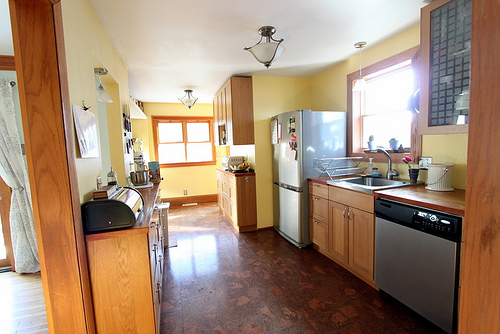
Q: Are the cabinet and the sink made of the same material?
A: No, the cabinet is made of wood and the sink is made of metal.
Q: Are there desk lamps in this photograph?
A: No, there are no desk lamps.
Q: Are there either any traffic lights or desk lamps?
A: No, there are no desk lamps or traffic lights.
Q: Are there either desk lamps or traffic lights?
A: No, there are no desk lamps or traffic lights.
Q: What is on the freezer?
A: The magnets are on the freezer.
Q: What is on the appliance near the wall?
A: The magnets are on the freezer.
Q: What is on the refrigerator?
A: The magnets are on the freezer.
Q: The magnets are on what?
A: The magnets are on the refrigerator.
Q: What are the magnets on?
A: The magnets are on the refrigerator.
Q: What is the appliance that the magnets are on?
A: The appliance is a refrigerator.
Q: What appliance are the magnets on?
A: The magnets are on the freezer.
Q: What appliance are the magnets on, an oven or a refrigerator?
A: The magnets are on a refrigerator.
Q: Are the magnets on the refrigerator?
A: Yes, the magnets are on the refrigerator.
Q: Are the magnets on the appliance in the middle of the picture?
A: Yes, the magnets are on the refrigerator.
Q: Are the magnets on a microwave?
A: No, the magnets are on the refrigerator.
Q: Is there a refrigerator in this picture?
A: Yes, there is a refrigerator.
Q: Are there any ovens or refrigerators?
A: Yes, there is a refrigerator.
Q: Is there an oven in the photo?
A: No, there are no ovens.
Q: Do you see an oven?
A: No, there are no ovens.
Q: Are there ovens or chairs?
A: No, there are no ovens or chairs.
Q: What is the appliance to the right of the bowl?
A: The appliance is a refrigerator.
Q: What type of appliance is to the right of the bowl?
A: The appliance is a refrigerator.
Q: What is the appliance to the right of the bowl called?
A: The appliance is a refrigerator.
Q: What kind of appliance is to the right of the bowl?
A: The appliance is a refrigerator.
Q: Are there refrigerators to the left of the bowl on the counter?
A: No, the refrigerator is to the right of the bowl.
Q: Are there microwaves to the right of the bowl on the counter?
A: No, there is a refrigerator to the right of the bowl.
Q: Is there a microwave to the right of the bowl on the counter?
A: No, there is a refrigerator to the right of the bowl.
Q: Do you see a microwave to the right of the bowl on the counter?
A: No, there is a refrigerator to the right of the bowl.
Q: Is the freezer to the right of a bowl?
A: Yes, the freezer is to the right of a bowl.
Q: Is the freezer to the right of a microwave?
A: No, the freezer is to the right of a bowl.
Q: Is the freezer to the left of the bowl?
A: No, the freezer is to the right of the bowl.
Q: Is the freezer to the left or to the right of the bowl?
A: The freezer is to the right of the bowl.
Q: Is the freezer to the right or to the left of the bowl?
A: The freezer is to the right of the bowl.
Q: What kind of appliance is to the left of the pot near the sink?
A: The appliance is a refrigerator.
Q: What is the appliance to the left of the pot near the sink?
A: The appliance is a refrigerator.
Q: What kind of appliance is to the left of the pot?
A: The appliance is a refrigerator.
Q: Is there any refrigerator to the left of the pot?
A: Yes, there is a refrigerator to the left of the pot.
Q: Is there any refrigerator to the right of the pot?
A: No, the refrigerator is to the left of the pot.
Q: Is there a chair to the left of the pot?
A: No, there is a refrigerator to the left of the pot.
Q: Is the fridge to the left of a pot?
A: Yes, the fridge is to the left of a pot.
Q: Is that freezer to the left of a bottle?
A: No, the freezer is to the left of a pot.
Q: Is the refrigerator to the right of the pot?
A: No, the refrigerator is to the left of the pot.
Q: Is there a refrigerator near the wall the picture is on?
A: Yes, there is a refrigerator near the wall.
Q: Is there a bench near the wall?
A: No, there is a refrigerator near the wall.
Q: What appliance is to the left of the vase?
A: The appliance is a refrigerator.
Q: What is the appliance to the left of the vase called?
A: The appliance is a refrigerator.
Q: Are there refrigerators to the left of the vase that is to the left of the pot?
A: Yes, there is a refrigerator to the left of the vase.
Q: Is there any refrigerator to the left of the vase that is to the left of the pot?
A: Yes, there is a refrigerator to the left of the vase.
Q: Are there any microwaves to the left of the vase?
A: No, there is a refrigerator to the left of the vase.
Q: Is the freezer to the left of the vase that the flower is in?
A: Yes, the freezer is to the left of the vase.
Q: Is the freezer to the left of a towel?
A: No, the freezer is to the left of the vase.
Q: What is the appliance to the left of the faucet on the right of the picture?
A: The appliance is a refrigerator.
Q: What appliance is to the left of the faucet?
A: The appliance is a refrigerator.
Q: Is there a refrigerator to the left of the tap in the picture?
A: Yes, there is a refrigerator to the left of the tap.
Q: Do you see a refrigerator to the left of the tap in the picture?
A: Yes, there is a refrigerator to the left of the tap.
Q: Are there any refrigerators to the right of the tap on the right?
A: No, the refrigerator is to the left of the tap.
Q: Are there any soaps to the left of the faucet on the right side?
A: No, there is a refrigerator to the left of the tap.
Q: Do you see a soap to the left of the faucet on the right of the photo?
A: No, there is a refrigerator to the left of the tap.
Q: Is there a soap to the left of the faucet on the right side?
A: No, there is a refrigerator to the left of the tap.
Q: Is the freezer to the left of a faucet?
A: Yes, the freezer is to the left of a faucet.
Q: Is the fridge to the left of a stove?
A: No, the fridge is to the left of a faucet.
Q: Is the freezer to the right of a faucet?
A: No, the freezer is to the left of a faucet.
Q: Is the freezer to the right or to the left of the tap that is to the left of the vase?
A: The freezer is to the left of the faucet.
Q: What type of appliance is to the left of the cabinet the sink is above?
A: The appliance is a refrigerator.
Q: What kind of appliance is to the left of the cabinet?
A: The appliance is a refrigerator.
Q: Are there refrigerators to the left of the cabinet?
A: Yes, there is a refrigerator to the left of the cabinet.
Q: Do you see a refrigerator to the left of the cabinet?
A: Yes, there is a refrigerator to the left of the cabinet.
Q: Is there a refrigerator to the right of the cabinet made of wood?
A: No, the refrigerator is to the left of the cabinet.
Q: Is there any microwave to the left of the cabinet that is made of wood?
A: No, there is a refrigerator to the left of the cabinet.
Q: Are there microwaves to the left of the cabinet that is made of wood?
A: No, there is a refrigerator to the left of the cabinet.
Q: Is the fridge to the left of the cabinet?
A: Yes, the fridge is to the left of the cabinet.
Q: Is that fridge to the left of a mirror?
A: No, the fridge is to the left of the cabinet.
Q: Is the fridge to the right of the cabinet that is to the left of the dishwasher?
A: No, the fridge is to the left of the cabinet.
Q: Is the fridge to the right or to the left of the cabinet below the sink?
A: The fridge is to the left of the cabinet.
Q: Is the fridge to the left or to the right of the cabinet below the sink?
A: The fridge is to the left of the cabinet.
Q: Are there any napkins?
A: No, there are no napkins.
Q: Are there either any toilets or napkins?
A: No, there are no napkins or toilets.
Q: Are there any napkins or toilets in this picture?
A: No, there are no napkins or toilets.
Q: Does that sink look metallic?
A: Yes, the sink is metallic.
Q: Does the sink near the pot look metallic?
A: Yes, the sink is metallic.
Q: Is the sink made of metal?
A: Yes, the sink is made of metal.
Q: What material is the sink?
A: The sink is made of metal.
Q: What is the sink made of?
A: The sink is made of metal.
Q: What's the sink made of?
A: The sink is made of metal.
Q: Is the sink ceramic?
A: No, the sink is metallic.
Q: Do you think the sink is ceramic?
A: No, the sink is metallic.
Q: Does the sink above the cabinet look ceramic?
A: No, the sink is metallic.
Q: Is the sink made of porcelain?
A: No, the sink is made of metal.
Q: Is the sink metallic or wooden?
A: The sink is metallic.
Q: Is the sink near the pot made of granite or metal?
A: The sink is made of metal.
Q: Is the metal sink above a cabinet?
A: Yes, the sink is above a cabinet.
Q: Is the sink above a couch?
A: No, the sink is above a cabinet.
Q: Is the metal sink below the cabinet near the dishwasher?
A: No, the sink is above the cabinet.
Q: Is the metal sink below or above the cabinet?
A: The sink is above the cabinet.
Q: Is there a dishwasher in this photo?
A: Yes, there is a dishwasher.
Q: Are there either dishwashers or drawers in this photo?
A: Yes, there is a dishwasher.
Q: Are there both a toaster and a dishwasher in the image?
A: No, there is a dishwasher but no toasters.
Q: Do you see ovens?
A: No, there are no ovens.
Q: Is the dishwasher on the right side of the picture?
A: Yes, the dishwasher is on the right of the image.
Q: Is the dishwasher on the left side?
A: No, the dishwasher is on the right of the image.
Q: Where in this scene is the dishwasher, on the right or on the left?
A: The dishwasher is on the right of the image.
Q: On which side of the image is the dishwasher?
A: The dishwasher is on the right of the image.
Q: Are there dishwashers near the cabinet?
A: Yes, there is a dishwasher near the cabinet.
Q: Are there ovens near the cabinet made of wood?
A: No, there is a dishwasher near the cabinet.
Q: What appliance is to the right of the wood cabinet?
A: The appliance is a dishwasher.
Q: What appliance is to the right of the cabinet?
A: The appliance is a dishwasher.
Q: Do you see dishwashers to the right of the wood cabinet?
A: Yes, there is a dishwasher to the right of the cabinet.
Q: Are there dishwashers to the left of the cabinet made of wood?
A: No, the dishwasher is to the right of the cabinet.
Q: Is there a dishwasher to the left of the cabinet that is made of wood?
A: No, the dishwasher is to the right of the cabinet.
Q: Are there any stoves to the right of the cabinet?
A: No, there is a dishwasher to the right of the cabinet.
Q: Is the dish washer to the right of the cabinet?
A: Yes, the dish washer is to the right of the cabinet.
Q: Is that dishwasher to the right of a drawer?
A: No, the dishwasher is to the right of the cabinet.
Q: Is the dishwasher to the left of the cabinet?
A: No, the dishwasher is to the right of the cabinet.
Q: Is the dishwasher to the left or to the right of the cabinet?
A: The dishwasher is to the right of the cabinet.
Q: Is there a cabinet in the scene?
A: Yes, there is a cabinet.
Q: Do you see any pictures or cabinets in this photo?
A: Yes, there is a cabinet.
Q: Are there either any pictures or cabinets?
A: Yes, there is a cabinet.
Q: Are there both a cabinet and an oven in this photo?
A: No, there is a cabinet but no ovens.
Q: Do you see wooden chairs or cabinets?
A: Yes, there is a wood cabinet.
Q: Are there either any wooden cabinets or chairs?
A: Yes, there is a wood cabinet.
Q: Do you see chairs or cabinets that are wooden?
A: Yes, the cabinet is wooden.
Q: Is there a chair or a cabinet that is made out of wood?
A: Yes, the cabinet is made of wood.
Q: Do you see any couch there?
A: No, there are no couches.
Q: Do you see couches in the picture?
A: No, there are no couches.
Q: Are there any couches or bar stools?
A: No, there are no couches or bar stools.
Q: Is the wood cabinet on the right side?
A: Yes, the cabinet is on the right of the image.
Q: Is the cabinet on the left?
A: No, the cabinet is on the right of the image.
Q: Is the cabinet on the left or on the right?
A: The cabinet is on the right of the image.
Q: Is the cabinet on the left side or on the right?
A: The cabinet is on the right of the image.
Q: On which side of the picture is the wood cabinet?
A: The cabinet is on the right of the image.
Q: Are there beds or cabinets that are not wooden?
A: No, there is a cabinet but it is wooden.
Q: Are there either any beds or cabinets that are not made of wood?
A: No, there is a cabinet but it is made of wood.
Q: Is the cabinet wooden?
A: Yes, the cabinet is wooden.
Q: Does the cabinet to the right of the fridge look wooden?
A: Yes, the cabinet is wooden.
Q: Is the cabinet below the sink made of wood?
A: Yes, the cabinet is made of wood.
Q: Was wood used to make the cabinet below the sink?
A: Yes, the cabinet is made of wood.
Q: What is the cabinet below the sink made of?
A: The cabinet is made of wood.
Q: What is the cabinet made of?
A: The cabinet is made of wood.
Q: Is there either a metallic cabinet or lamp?
A: No, there is a cabinet but it is wooden.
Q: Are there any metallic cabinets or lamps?
A: No, there is a cabinet but it is wooden.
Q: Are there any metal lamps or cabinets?
A: No, there is a cabinet but it is wooden.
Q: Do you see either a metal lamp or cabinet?
A: No, there is a cabinet but it is wooden.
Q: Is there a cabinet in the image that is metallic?
A: No, there is a cabinet but it is wooden.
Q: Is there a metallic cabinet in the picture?
A: No, there is a cabinet but it is wooden.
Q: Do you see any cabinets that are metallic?
A: No, there is a cabinet but it is wooden.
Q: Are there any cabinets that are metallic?
A: No, there is a cabinet but it is wooden.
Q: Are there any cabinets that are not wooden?
A: No, there is a cabinet but it is wooden.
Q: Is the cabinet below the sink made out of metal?
A: No, the cabinet is made of wood.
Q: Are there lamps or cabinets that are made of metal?
A: No, there is a cabinet but it is made of wood.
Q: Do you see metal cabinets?
A: No, there is a cabinet but it is made of wood.